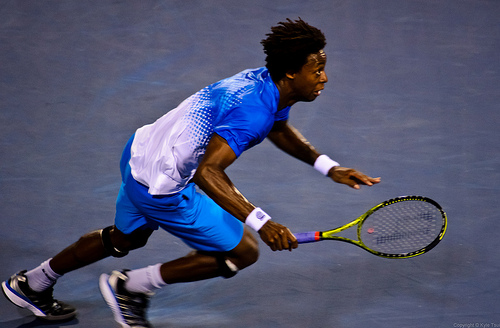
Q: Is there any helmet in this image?
A: No, there are no helmets.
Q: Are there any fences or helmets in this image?
A: No, there are no helmets or fences.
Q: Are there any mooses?
A: No, there are no mooses.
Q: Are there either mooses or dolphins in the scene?
A: No, there are no mooses or dolphins.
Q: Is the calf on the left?
A: Yes, the calf is on the left of the image.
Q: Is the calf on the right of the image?
A: No, the calf is on the left of the image.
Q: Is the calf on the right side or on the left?
A: The calf is on the left of the image.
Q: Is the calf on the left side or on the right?
A: The calf is on the left of the image.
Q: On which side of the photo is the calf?
A: The calf is on the left of the image.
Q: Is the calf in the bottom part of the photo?
A: Yes, the calf is in the bottom of the image.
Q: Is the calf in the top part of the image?
A: No, the calf is in the bottom of the image.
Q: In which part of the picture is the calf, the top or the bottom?
A: The calf is in the bottom of the image.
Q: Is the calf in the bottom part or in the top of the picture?
A: The calf is in the bottom of the image.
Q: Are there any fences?
A: No, there are no fences.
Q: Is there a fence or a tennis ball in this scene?
A: No, there are no fences or tennis balls.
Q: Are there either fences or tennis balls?
A: No, there are no fences or tennis balls.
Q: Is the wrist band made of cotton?
A: Yes, the wrist band is made of cotton.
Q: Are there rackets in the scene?
A: Yes, there is a racket.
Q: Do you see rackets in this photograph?
A: Yes, there is a racket.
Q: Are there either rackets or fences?
A: Yes, there is a racket.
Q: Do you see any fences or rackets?
A: Yes, there is a racket.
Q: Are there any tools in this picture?
A: No, there are no tools.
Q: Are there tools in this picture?
A: No, there are no tools.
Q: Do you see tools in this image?
A: No, there are no tools.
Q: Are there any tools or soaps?
A: No, there are no tools or soaps.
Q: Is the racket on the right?
A: Yes, the racket is on the right of the image.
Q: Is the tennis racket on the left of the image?
A: No, the tennis racket is on the right of the image.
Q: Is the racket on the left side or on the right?
A: The racket is on the right of the image.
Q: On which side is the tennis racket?
A: The tennis racket is on the right of the image.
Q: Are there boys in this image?
A: No, there are no boys.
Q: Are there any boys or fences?
A: No, there are no boys or fences.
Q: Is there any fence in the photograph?
A: No, there are no fences.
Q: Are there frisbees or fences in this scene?
A: No, there are no fences or frisbees.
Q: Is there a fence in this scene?
A: No, there are no fences.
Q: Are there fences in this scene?
A: No, there are no fences.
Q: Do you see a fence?
A: No, there are no fences.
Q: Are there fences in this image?
A: No, there are no fences.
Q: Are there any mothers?
A: No, there are no mothers.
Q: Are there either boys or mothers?
A: No, there are no mothers or boys.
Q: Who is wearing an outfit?
A: The athlete is wearing an outfit.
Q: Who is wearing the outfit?
A: The athlete is wearing an outfit.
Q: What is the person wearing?
A: The athlete is wearing an outfit.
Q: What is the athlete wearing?
A: The athlete is wearing an outfit.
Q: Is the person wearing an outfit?
A: Yes, the athlete is wearing an outfit.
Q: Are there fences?
A: No, there are no fences.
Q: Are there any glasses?
A: No, there are no glasses.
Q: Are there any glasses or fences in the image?
A: No, there are no glasses or fences.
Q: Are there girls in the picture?
A: No, there are no girls.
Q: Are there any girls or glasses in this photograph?
A: No, there are no girls or glasses.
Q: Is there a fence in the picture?
A: No, there are no fences.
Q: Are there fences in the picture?
A: No, there are no fences.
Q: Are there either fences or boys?
A: No, there are no fences or boys.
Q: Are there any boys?
A: No, there are no boys.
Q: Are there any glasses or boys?
A: No, there are no boys or glasses.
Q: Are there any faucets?
A: No, there are no faucets.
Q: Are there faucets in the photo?
A: No, there are no faucets.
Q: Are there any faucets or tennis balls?
A: No, there are no faucets or tennis balls.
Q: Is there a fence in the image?
A: No, there are no fences.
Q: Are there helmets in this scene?
A: No, there are no helmets.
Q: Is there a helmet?
A: No, there are no helmets.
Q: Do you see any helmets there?
A: No, there are no helmets.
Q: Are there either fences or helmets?
A: No, there are no helmets or fences.